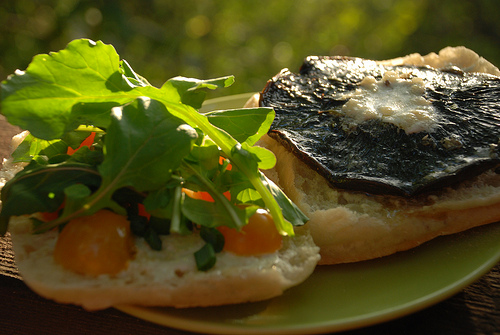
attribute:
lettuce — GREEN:
[46, 63, 134, 95]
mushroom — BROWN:
[281, 61, 482, 184]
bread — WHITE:
[325, 196, 357, 229]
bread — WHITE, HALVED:
[301, 187, 364, 245]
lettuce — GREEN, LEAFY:
[38, 57, 215, 203]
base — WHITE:
[360, 73, 416, 124]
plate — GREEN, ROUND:
[321, 265, 405, 323]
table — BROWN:
[446, 297, 476, 325]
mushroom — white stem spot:
[265, 38, 478, 192]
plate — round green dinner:
[330, 257, 442, 316]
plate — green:
[327, 281, 399, 320]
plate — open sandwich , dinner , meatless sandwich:
[10, 23, 484, 321]